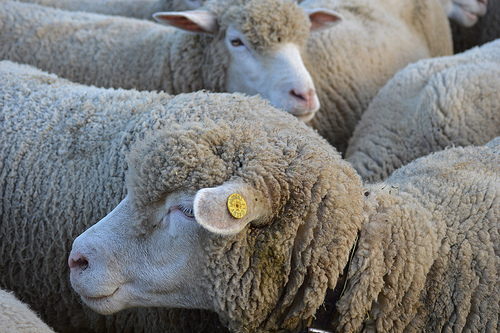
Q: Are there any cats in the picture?
A: No, there are no cats.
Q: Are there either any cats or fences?
A: No, there are no cats or fences.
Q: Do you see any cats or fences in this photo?
A: No, there are no cats or fences.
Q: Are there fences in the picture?
A: No, there are no fences.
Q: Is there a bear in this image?
A: No, there are no bears.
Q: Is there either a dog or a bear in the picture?
A: No, there are no bears or dogs.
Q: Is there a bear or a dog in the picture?
A: No, there are no bears or dogs.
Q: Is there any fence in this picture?
A: No, there are no fences.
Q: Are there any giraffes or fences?
A: No, there are no fences or giraffes.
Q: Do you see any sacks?
A: No, there are no sacks.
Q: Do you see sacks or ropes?
A: No, there are no sacks or ropes.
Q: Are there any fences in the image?
A: No, there are no fences.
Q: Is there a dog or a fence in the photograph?
A: No, there are no fences or dogs.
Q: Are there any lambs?
A: Yes, there is a lamb.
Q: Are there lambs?
A: Yes, there is a lamb.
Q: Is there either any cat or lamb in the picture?
A: Yes, there is a lamb.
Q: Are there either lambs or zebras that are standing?
A: Yes, the lamb is standing.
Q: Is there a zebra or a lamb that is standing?
A: Yes, the lamb is standing.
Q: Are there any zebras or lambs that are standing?
A: Yes, the lamb is standing.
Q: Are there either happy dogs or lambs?
A: Yes, there is a happy lamb.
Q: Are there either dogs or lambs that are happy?
A: Yes, the lamb is happy.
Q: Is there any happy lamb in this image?
A: Yes, there is a happy lamb.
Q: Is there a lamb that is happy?
A: Yes, there is a lamb that is happy.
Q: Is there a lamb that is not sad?
A: Yes, there is a happy lamb.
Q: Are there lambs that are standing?
A: Yes, there is a lamb that is standing.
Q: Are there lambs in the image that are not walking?
A: Yes, there is a lamb that is standing.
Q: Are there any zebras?
A: No, there are no zebras.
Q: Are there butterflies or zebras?
A: No, there are no zebras or butterflies.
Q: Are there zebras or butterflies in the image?
A: No, there are no zebras or butterflies.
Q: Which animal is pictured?
A: The animal is a lamb.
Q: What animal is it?
A: The animal is a lamb.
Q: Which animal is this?
A: This is a lamb.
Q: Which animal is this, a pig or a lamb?
A: This is a lamb.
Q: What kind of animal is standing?
A: The animal is a lamb.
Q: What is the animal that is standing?
A: The animal is a lamb.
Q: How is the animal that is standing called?
A: The animal is a lamb.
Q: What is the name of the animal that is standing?
A: The animal is a lamb.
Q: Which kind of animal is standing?
A: The animal is a lamb.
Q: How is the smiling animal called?
A: The animal is a lamb.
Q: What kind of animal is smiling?
A: The animal is a lamb.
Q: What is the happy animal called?
A: The animal is a lamb.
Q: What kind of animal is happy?
A: The animal is a lamb.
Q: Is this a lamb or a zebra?
A: This is a lamb.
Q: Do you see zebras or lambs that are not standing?
A: No, there is a lamb but it is standing.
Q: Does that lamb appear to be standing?
A: Yes, the lamb is standing.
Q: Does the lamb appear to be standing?
A: Yes, the lamb is standing.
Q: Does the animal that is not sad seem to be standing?
A: Yes, the lamb is standing.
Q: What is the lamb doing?
A: The lamb is standing.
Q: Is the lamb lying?
A: No, the lamb is standing.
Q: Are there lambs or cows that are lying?
A: No, there is a lamb but it is standing.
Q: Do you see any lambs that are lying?
A: No, there is a lamb but it is standing.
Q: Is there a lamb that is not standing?
A: No, there is a lamb but it is standing.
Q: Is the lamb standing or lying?
A: The lamb is standing.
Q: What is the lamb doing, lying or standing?
A: The lamb is standing.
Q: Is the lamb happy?
A: Yes, the lamb is happy.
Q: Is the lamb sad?
A: No, the lamb is happy.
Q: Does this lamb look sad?
A: No, the lamb is happy.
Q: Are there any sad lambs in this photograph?
A: No, there is a lamb but it is happy.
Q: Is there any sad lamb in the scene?
A: No, there is a lamb but it is happy.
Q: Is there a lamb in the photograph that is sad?
A: No, there is a lamb but it is happy.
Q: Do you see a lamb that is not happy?
A: No, there is a lamb but it is happy.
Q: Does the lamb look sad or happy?
A: The lamb is happy.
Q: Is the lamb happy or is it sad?
A: The lamb is happy.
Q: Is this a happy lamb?
A: Yes, this is a happy lamb.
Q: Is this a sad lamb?
A: No, this is a happy lamb.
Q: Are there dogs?
A: No, there are no dogs.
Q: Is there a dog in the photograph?
A: No, there are no dogs.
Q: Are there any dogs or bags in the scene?
A: No, there are no dogs or bags.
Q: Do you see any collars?
A: Yes, there is a collar.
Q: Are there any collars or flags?
A: Yes, there is a collar.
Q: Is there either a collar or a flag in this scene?
A: Yes, there is a collar.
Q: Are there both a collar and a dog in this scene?
A: No, there is a collar but no dogs.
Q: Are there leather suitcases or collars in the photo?
A: Yes, there is a leather collar.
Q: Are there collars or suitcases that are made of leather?
A: Yes, the collar is made of leather.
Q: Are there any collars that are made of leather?
A: Yes, there is a collar that is made of leather.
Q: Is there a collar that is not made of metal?
A: Yes, there is a collar that is made of leather.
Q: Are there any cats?
A: No, there are no cats.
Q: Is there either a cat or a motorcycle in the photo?
A: No, there are no cats or motorcycles.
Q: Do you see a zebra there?
A: No, there are no zebras.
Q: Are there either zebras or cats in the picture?
A: No, there are no zebras or cats.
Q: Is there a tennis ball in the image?
A: No, there are no tennis balls.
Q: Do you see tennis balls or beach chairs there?
A: No, there are no tennis balls or beach chairs.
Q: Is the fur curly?
A: Yes, the fur is curly.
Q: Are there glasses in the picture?
A: No, there are no glasses.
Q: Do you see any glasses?
A: No, there are no glasses.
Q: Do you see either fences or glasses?
A: No, there are no glasses or fences.